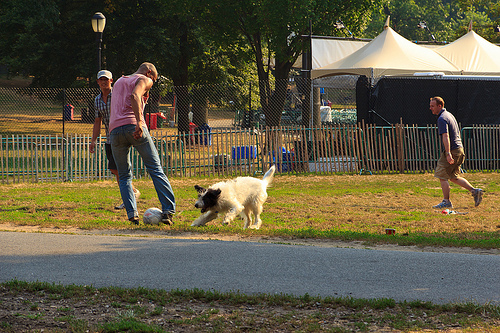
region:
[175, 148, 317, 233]
beautiful black and white adult dog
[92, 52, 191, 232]
person wearing pink tee shirt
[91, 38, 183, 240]
person wearing blue jeans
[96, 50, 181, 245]
person kicking soccer ball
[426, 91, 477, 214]
man wearing blue short sleeve tee shirt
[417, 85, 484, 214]
man wearing brown shorts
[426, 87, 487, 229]
man wearing pair of tennis shoes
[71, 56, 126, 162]
man wearing white baseball cap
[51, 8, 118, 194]
nice black lamp with glass globe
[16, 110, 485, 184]
wire silver fence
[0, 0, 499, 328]
A park scene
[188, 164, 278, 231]
A dog is in the park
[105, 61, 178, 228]
This man is playing with a ball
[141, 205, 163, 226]
A soccer ball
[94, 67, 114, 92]
This man is wearing a hat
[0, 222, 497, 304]
A paved path is in the park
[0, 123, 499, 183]
A fence is behind the men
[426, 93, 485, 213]
This man is walking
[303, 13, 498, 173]
A tent is in the background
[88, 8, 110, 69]
A lamp post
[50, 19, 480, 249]
having fun in a park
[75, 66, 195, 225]
playing soccer with a friend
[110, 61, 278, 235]
the dog is playing soccer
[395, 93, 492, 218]
this man is looking at the action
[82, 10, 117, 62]
a lampost in the area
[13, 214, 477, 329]
a jogging trail for runners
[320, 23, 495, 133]
a tent in the area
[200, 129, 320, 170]
blue objects on the ground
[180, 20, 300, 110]
trees in the area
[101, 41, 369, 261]
Man with a dog.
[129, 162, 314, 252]
dog trying to get a ball.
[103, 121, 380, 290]
dog by the man.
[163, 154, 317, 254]
Black and white dog.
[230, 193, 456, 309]
Grass by the road.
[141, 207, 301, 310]
Road between the grasses.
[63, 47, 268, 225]
Man with a pink shirt.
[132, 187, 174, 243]
White ball on the ground.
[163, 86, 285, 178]
Fence in the background.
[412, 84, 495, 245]
Man on the grass.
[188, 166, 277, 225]
A brown and white dog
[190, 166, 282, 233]
A brown and white dog playing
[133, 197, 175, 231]
A soccer ball on the grass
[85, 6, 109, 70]
A tall black lamppost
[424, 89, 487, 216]
A man standing in the grass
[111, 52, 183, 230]
A man playing soccer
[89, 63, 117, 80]
A white baseball hat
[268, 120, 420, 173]
Brown fencing around the grassy area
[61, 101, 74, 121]
A garbage can in the distance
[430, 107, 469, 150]
A blue polo shirt